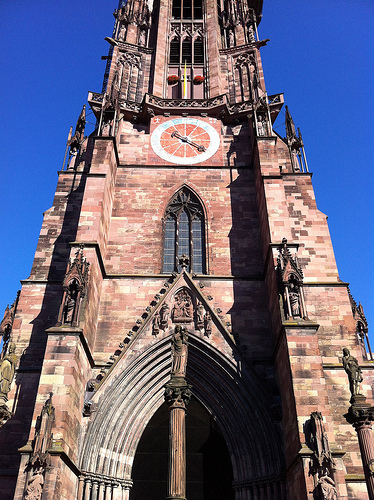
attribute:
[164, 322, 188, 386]
statute — brown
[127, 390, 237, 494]
doorway — arched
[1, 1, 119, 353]
blue sky — dark blue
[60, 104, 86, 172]
spires — decorative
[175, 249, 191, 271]
cross — small, thick, decorative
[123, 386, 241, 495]
arched doorway — atched, layered, stone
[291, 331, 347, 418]
building — red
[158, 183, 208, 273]
window — glass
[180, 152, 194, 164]
number — blue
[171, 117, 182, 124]
number — blue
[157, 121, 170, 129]
number — blue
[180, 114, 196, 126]
number — blue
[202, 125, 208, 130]
number — blue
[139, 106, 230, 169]
clock — white, round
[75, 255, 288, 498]
door — arched, entry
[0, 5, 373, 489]
tower — tall, brick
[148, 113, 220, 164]
clock — white, circular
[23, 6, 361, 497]
building — big, old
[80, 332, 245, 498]
door — entry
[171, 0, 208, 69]
tower — open, bell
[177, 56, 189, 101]
needle — yellow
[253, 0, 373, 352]
sky — dark blue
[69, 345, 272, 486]
doorway — alcove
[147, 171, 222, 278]
window — decorative